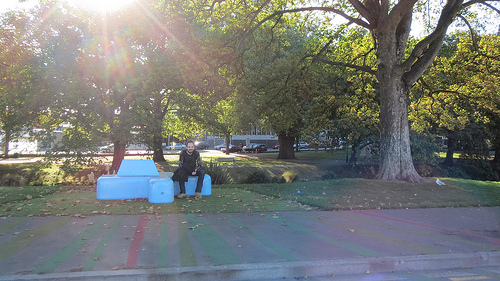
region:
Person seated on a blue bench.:
[171, 133, 206, 198]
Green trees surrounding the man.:
[8, 6, 496, 187]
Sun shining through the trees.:
[36, 1, 208, 72]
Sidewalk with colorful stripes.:
[1, 201, 496, 277]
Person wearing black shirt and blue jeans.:
[177, 148, 204, 194]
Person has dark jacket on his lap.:
[171, 165, 187, 182]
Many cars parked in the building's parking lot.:
[197, 140, 333, 150]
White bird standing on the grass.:
[430, 170, 448, 191]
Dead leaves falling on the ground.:
[20, 193, 411, 216]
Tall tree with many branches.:
[289, 2, 495, 187]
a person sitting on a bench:
[54, 107, 281, 276]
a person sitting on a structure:
[41, 115, 223, 219]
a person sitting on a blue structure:
[67, 109, 251, 232]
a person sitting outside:
[91, 141, 219, 206]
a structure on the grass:
[8, 97, 296, 260]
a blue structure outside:
[37, 108, 322, 213]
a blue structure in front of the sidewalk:
[87, 147, 339, 279]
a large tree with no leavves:
[298, 5, 498, 260]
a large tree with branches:
[319, 6, 494, 250]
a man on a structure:
[86, 133, 281, 249]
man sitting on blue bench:
[171, 138, 210, 200]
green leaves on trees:
[4, 2, 499, 152]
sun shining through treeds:
[61, 0, 158, 35]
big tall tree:
[329, 1, 464, 188]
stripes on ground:
[17, 215, 498, 259]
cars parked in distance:
[182, 143, 279, 156]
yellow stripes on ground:
[1, 210, 61, 270]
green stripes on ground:
[39, 209, 126, 277]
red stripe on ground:
[122, 210, 143, 270]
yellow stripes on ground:
[331, 206, 445, 264]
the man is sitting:
[172, 129, 217, 206]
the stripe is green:
[217, 209, 297, 267]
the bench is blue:
[94, 146, 173, 210]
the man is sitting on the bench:
[159, 120, 223, 204]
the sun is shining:
[52, 2, 159, 29]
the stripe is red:
[116, 209, 151, 262]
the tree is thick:
[360, 35, 435, 178]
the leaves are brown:
[47, 183, 92, 233]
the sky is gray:
[404, 17, 441, 34]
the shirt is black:
[175, 150, 207, 174]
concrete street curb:
[32, 258, 494, 275]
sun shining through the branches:
[71, 0, 144, 16]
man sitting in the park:
[171, 141, 207, 197]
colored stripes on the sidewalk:
[1, 215, 481, 266]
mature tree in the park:
[326, 0, 487, 187]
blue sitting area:
[96, 160, 211, 200]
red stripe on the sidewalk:
[126, 213, 151, 268]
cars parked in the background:
[221, 143, 281, 150]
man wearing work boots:
[172, 189, 202, 199]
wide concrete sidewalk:
[2, 214, 497, 276]